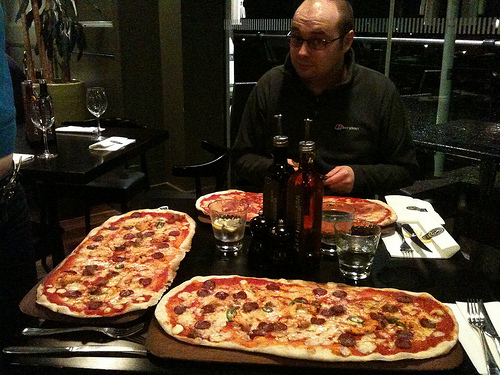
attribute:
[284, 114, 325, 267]
bottle — liquor bottle, brown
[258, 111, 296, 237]
bottle — liquor bottle, brown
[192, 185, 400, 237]
pizza — baked, oblong, huge, large, resting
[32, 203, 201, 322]
pizza — baked, oblong, huge, large, resting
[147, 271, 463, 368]
pizza — baked, oblong, huge, large, resting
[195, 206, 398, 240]
board — wooden